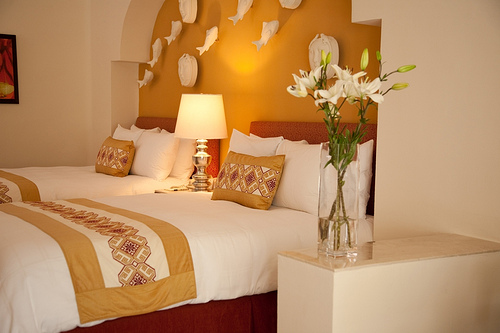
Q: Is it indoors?
A: Yes, it is indoors.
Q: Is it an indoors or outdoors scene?
A: It is indoors.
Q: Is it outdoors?
A: No, it is indoors.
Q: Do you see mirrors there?
A: No, there are no mirrors.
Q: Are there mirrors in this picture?
A: No, there are no mirrors.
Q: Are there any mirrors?
A: No, there are no mirrors.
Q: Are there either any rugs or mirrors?
A: No, there are no mirrors or rugs.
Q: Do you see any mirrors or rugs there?
A: No, there are no mirrors or rugs.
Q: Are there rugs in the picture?
A: No, there are no rugs.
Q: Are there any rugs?
A: No, there are no rugs.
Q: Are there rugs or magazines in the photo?
A: No, there are no rugs or magazines.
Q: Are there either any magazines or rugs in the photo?
A: No, there are no rugs or magazines.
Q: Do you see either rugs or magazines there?
A: No, there are no rugs or magazines.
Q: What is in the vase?
A: The flowers are in the vase.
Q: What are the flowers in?
A: The flowers are in the vase.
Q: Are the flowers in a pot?
A: No, the flowers are in the vase.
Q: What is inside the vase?
A: The flowers are inside the vase.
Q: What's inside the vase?
A: The flowers are inside the vase.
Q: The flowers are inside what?
A: The flowers are inside the vase.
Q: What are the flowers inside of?
A: The flowers are inside the vase.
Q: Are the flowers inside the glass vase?
A: Yes, the flowers are inside the vase.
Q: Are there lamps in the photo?
A: Yes, there is a lamp.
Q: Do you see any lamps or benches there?
A: Yes, there is a lamp.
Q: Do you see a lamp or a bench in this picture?
A: Yes, there is a lamp.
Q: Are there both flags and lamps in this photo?
A: No, there is a lamp but no flags.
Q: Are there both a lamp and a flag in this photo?
A: No, there is a lamp but no flags.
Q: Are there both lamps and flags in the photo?
A: No, there is a lamp but no flags.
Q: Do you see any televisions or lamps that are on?
A: Yes, the lamp is on.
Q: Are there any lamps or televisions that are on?
A: Yes, the lamp is on.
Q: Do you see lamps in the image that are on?
A: Yes, there is a lamp that is on.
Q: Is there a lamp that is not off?
A: Yes, there is a lamp that is on.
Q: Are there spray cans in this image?
A: No, there are no spray cans.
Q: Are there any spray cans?
A: No, there are no spray cans.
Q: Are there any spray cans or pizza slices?
A: No, there are no spray cans or pizza slices.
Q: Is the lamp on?
A: Yes, the lamp is on.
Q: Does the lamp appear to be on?
A: Yes, the lamp is on.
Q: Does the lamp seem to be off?
A: No, the lamp is on.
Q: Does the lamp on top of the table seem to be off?
A: No, the lamp is on.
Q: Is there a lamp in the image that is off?
A: No, there is a lamp but it is on.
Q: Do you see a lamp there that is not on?
A: No, there is a lamp but it is on.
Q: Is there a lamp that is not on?
A: No, there is a lamp but it is on.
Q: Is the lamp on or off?
A: The lamp is on.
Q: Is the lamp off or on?
A: The lamp is on.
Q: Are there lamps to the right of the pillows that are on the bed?
A: Yes, there is a lamp to the right of the pillows.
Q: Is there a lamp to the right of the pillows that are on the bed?
A: Yes, there is a lamp to the right of the pillows.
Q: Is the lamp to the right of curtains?
A: No, the lamp is to the right of the pillows.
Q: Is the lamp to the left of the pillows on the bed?
A: No, the lamp is to the right of the pillows.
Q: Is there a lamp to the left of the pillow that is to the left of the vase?
A: Yes, there is a lamp to the left of the pillow.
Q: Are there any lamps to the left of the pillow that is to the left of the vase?
A: Yes, there is a lamp to the left of the pillow.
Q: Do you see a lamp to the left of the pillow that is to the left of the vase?
A: Yes, there is a lamp to the left of the pillow.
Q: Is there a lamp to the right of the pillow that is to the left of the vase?
A: No, the lamp is to the left of the pillow.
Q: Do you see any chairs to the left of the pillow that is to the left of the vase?
A: No, there is a lamp to the left of the pillow.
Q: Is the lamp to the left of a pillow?
A: Yes, the lamp is to the left of a pillow.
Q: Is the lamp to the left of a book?
A: No, the lamp is to the left of a pillow.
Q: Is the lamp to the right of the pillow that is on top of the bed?
A: No, the lamp is to the left of the pillow.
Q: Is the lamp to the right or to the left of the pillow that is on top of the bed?
A: The lamp is to the left of the pillow.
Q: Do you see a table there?
A: Yes, there is a table.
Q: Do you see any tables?
A: Yes, there is a table.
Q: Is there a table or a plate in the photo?
A: Yes, there is a table.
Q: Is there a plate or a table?
A: Yes, there is a table.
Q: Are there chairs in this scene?
A: No, there are no chairs.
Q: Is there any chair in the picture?
A: No, there are no chairs.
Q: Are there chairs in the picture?
A: No, there are no chairs.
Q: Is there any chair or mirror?
A: No, there are no chairs or mirrors.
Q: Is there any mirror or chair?
A: No, there are no chairs or mirrors.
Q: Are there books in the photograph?
A: No, there are no books.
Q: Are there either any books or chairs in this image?
A: No, there are no books or chairs.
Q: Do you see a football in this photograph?
A: No, there are no footballs.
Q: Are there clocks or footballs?
A: No, there are no footballs or clocks.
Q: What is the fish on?
A: The fish is on the wall.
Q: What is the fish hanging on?
A: The fish is hanging on the wall.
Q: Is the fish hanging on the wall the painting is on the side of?
A: Yes, the fish is hanging on the wall.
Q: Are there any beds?
A: Yes, there is a bed.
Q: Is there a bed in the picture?
A: Yes, there is a bed.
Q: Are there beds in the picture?
A: Yes, there is a bed.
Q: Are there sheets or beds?
A: Yes, there is a bed.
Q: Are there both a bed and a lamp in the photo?
A: Yes, there are both a bed and a lamp.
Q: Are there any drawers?
A: No, there are no drawers.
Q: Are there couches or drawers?
A: No, there are no drawers or couches.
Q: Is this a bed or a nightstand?
A: This is a bed.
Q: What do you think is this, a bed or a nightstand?
A: This is a bed.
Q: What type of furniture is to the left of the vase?
A: The piece of furniture is a bed.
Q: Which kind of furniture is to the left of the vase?
A: The piece of furniture is a bed.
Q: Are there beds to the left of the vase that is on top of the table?
A: Yes, there is a bed to the left of the vase.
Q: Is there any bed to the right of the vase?
A: No, the bed is to the left of the vase.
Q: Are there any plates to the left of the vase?
A: No, there is a bed to the left of the vase.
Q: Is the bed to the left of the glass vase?
A: Yes, the bed is to the left of the vase.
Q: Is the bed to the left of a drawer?
A: No, the bed is to the left of the vase.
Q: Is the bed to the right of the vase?
A: No, the bed is to the left of the vase.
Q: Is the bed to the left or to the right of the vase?
A: The bed is to the left of the vase.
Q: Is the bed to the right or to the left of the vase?
A: The bed is to the left of the vase.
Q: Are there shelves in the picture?
A: No, there are no shelves.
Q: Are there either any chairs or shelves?
A: No, there are no shelves or chairs.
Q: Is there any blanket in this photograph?
A: Yes, there is a blanket.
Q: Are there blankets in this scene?
A: Yes, there is a blanket.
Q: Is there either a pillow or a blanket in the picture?
A: Yes, there is a blanket.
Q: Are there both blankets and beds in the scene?
A: Yes, there are both a blanket and a bed.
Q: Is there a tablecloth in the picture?
A: No, there are no tablecloths.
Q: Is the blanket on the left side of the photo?
A: Yes, the blanket is on the left of the image.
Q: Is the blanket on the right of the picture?
A: No, the blanket is on the left of the image.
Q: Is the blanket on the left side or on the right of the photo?
A: The blanket is on the left of the image.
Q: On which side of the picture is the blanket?
A: The blanket is on the left of the image.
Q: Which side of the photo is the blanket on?
A: The blanket is on the left of the image.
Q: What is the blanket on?
A: The blanket is on the bed.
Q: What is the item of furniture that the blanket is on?
A: The piece of furniture is a bed.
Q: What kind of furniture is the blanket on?
A: The blanket is on the bed.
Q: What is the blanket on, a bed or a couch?
A: The blanket is on a bed.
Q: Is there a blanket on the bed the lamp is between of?
A: Yes, there is a blanket on the bed.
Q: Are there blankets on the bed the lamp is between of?
A: Yes, there is a blanket on the bed.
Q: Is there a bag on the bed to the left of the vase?
A: No, there is a blanket on the bed.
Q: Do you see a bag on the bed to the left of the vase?
A: No, there is a blanket on the bed.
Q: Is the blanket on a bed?
A: Yes, the blanket is on a bed.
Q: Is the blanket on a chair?
A: No, the blanket is on a bed.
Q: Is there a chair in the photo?
A: No, there are no chairs.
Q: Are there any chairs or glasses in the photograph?
A: No, there are no chairs or glasses.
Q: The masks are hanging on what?
A: The masks are hanging on the wall.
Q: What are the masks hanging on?
A: The masks are hanging on the wall.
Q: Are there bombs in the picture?
A: No, there are no bombs.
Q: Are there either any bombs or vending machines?
A: No, there are no bombs or vending machines.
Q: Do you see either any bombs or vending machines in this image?
A: No, there are no bombs or vending machines.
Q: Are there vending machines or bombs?
A: No, there are no bombs or vending machines.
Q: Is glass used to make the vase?
A: Yes, the vase is made of glass.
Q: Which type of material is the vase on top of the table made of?
A: The vase is made of glass.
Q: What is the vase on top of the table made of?
A: The vase is made of glass.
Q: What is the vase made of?
A: The vase is made of glass.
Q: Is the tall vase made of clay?
A: No, the vase is made of glass.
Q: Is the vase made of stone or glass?
A: The vase is made of glass.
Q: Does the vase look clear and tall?
A: Yes, the vase is clear and tall.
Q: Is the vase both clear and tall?
A: Yes, the vase is clear and tall.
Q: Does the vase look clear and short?
A: No, the vase is clear but tall.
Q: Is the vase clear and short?
A: No, the vase is clear but tall.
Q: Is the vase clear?
A: Yes, the vase is clear.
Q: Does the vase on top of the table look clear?
A: Yes, the vase is clear.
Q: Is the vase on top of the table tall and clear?
A: Yes, the vase is tall and clear.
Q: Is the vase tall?
A: Yes, the vase is tall.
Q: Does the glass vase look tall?
A: Yes, the vase is tall.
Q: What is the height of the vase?
A: The vase is tall.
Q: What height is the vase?
A: The vase is tall.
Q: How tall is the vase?
A: The vase is tall.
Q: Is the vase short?
A: No, the vase is tall.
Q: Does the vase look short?
A: No, the vase is tall.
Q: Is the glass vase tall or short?
A: The vase is tall.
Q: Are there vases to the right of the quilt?
A: Yes, there is a vase to the right of the quilt.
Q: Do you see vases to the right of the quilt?
A: Yes, there is a vase to the right of the quilt.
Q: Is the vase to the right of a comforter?
A: Yes, the vase is to the right of a comforter.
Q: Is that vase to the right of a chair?
A: No, the vase is to the right of a comforter.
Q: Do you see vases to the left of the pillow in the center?
A: No, the vase is to the right of the pillow.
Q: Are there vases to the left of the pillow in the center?
A: No, the vase is to the right of the pillow.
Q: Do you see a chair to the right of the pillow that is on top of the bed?
A: No, there is a vase to the right of the pillow.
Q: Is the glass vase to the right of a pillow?
A: Yes, the vase is to the right of a pillow.